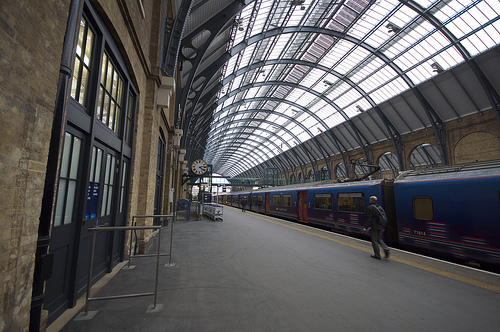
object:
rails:
[127, 215, 175, 269]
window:
[321, 166, 329, 180]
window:
[222, 0, 500, 95]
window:
[408, 142, 444, 167]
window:
[377, 151, 400, 171]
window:
[335, 163, 347, 178]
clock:
[191, 159, 208, 175]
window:
[52, 131, 83, 229]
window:
[413, 195, 434, 220]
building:
[0, 0, 499, 332]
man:
[363, 195, 390, 260]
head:
[370, 196, 378, 204]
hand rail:
[84, 226, 162, 312]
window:
[85, 145, 104, 219]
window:
[299, 172, 305, 182]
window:
[291, 174, 296, 183]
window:
[94, 56, 129, 128]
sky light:
[205, 0, 497, 177]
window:
[355, 158, 370, 175]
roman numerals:
[199, 161, 201, 163]